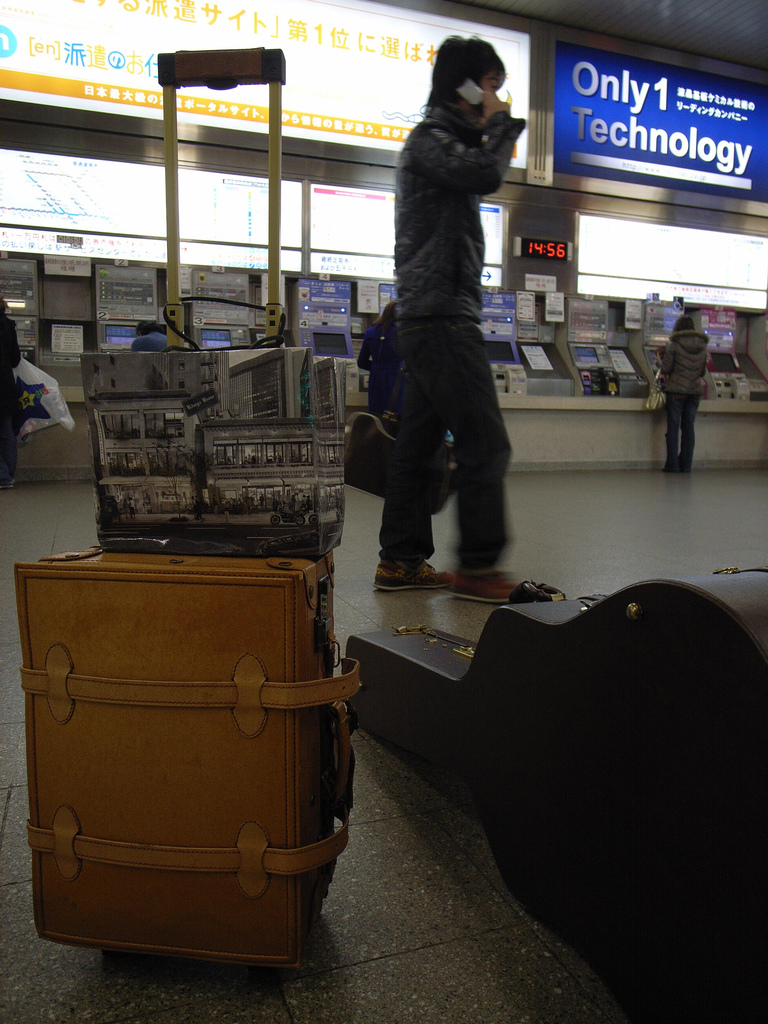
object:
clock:
[511, 232, 575, 264]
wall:
[0, 0, 768, 471]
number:
[298, 318, 309, 327]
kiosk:
[286, 272, 363, 371]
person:
[657, 307, 713, 477]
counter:
[369, 395, 765, 474]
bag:
[78, 311, 360, 572]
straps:
[267, 805, 358, 881]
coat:
[387, 113, 530, 340]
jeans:
[367, 299, 517, 598]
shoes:
[364, 541, 459, 600]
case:
[346, 557, 764, 1022]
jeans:
[661, 392, 702, 477]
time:
[527, 238, 568, 259]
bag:
[2, 351, 78, 447]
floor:
[0, 473, 764, 1024]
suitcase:
[0, 517, 366, 992]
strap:
[260, 649, 371, 720]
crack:
[372, 934, 483, 961]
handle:
[147, 40, 299, 360]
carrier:
[100, 43, 342, 564]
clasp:
[390, 618, 430, 638]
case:
[329, 389, 477, 525]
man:
[361, 16, 547, 624]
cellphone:
[455, 76, 488, 112]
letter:
[567, 54, 603, 104]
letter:
[595, 72, 620, 108]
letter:
[617, 65, 636, 106]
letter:
[623, 76, 656, 119]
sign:
[560, 52, 758, 183]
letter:
[568, 101, 595, 146]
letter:
[608, 116, 629, 151]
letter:
[648, 122, 672, 157]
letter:
[667, 124, 691, 163]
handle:
[230, 809, 275, 909]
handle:
[45, 792, 87, 887]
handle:
[95, 529, 189, 566]